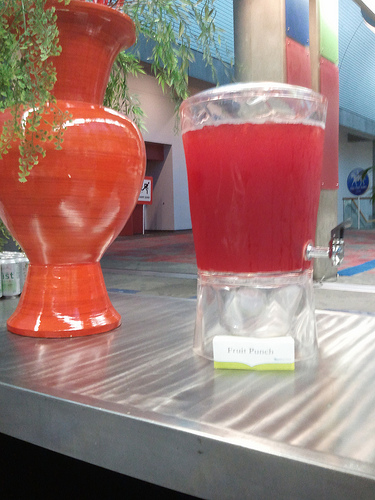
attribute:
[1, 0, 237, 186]
leaves — small, green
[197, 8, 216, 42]
leaf — green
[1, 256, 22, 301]
beverages — canned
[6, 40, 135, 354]
planter — large, ceramic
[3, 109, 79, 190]
plant — green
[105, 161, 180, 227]
sign — red, white, black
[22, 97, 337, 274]
leaf — small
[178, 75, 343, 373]
jug — plastic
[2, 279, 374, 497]
table — metal, shiny, silver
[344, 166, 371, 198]
painting — blue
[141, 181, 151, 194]
figure — running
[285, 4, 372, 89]
tiles — colored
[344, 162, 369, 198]
sign — circular, blue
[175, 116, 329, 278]
punch — red fruit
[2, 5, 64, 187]
plant — green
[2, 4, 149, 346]
vase — orange, large, red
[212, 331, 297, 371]
sign — white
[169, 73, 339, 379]
jar — big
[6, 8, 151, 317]
vase — orange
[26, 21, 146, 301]
pot — orange, old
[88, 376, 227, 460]
counter — metal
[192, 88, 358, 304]
dispenser — metal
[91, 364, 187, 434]
table — grey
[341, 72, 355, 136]
wall — grey, blue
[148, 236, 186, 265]
floor — red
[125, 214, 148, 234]
door — red